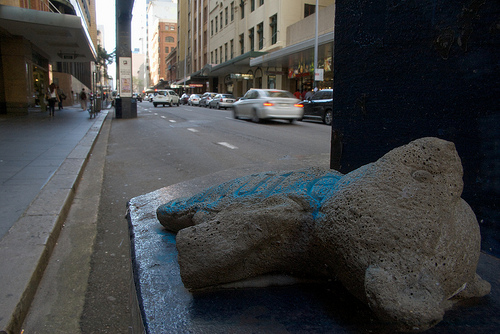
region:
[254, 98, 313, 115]
headlights on a car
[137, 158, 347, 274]
blue painted rocks on platformm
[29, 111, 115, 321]
curb of a sidewalk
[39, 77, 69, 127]
person in white shirt and black pants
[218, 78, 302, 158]
white car on road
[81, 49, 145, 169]
side on side of street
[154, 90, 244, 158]
white lines on road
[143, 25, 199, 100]
tall red brick building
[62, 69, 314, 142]
vehicles on street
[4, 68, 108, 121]
pedestrians on a sidewalk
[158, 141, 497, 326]
stone bear statute on sidewalk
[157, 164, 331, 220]
blue paint on bear statute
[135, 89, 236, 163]
white dotted line on street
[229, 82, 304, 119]
white car driving down street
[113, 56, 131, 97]
white street signs on square column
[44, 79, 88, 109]
people walking down sidewalk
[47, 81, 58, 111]
person wearing white shirt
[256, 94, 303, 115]
red brake lights of white car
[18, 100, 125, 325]
curb of the sidewalk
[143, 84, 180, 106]
suv turning down street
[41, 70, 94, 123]
People in the background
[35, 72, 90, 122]
People are walking on the sidewalk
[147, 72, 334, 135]
Cars in the street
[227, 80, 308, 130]
A white car in the background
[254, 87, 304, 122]
Car's taillights are on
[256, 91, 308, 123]
Car's taillights are red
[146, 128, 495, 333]
A stone object in the foreground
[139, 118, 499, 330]
Stone object is in the shape of a bear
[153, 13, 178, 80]
A brown building in the background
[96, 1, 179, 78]
The sky is clear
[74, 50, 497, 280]
a teddy bear that is outside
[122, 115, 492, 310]
a dirty teddy bear that is outside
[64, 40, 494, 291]
a teddy bear on a blue platform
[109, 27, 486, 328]
a dirty teddy bear on a blue platform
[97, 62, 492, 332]
a teddy bear on a platform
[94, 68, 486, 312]
a dirty teddy bear on a plateform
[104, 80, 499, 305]
a dirty brown teddy bear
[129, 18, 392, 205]
cars on a road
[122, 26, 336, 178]
cars on a street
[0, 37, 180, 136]
people on a sidewalk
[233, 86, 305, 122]
white car driving on a city street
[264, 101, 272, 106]
red tail light on car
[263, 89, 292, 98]
back window of car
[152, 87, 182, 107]
white vehicle is turning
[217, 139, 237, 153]
white lines on street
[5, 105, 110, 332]
curb to the left of street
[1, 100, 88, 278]
sidewalk next to curb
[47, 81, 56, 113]
person walking on sidewalk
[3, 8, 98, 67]
overhang over sidewalk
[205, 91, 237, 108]
car is parked